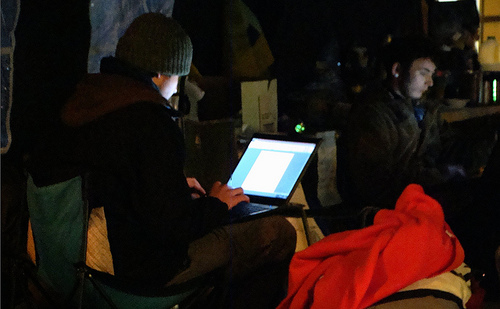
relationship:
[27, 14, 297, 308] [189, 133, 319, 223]
man holding laptop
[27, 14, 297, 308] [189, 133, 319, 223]
man looking at laptop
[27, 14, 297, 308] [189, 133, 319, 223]
man working on laptop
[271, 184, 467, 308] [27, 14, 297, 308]
blanket near man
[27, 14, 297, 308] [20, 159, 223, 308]
man in chair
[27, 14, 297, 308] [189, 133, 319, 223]
man on laptop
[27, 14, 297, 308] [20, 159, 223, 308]
man on chair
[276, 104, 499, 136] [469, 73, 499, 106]
table has boxes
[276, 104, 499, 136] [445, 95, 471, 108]
table has dishes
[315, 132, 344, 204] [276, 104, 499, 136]
paper on table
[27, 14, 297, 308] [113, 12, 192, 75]
man wearing hat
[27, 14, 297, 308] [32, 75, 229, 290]
man wearing coat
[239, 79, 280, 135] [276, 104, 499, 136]
menu on table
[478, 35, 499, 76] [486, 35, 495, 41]
jug with top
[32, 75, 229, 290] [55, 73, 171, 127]
coat has hood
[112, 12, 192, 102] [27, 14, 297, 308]
head of man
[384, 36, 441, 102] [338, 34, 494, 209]
head of man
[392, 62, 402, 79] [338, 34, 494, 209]
ear of man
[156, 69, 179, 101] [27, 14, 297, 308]
face of man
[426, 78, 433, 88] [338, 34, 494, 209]
nose of man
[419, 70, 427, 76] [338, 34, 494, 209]
eye of man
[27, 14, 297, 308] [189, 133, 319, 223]
man with laptop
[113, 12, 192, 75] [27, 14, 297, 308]
hat on man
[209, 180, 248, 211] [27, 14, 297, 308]
hand of man